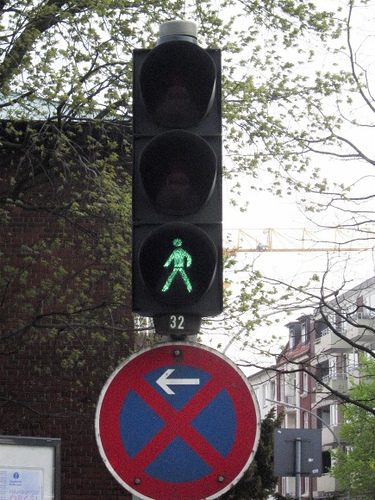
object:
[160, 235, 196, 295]
light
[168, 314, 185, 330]
number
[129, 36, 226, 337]
base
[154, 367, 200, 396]
arrow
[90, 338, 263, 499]
sign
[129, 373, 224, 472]
x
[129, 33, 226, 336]
light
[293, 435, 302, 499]
pole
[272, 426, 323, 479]
sign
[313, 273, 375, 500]
building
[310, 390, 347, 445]
stories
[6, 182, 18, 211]
tress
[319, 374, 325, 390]
branches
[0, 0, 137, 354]
tree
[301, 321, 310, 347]
windows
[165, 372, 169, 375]
spot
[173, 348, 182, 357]
screw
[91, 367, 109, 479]
edge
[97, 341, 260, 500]
circle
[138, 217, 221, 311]
signal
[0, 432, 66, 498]
sign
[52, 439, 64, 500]
edge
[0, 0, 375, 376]
sky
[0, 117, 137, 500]
building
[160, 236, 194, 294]
person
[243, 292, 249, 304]
leaves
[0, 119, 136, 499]
wall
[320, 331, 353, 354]
balcony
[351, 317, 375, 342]
balcony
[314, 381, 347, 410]
balcony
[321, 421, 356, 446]
balcony